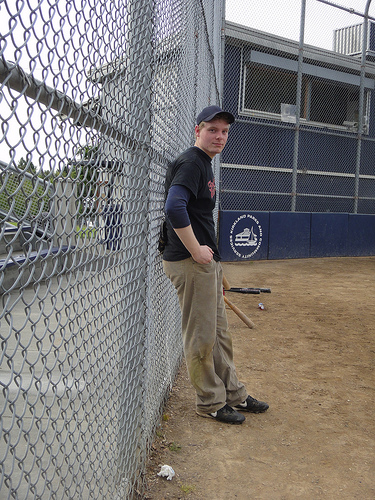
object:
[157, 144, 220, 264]
shirt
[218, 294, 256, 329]
baseball bat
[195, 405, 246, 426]
shoe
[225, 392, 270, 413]
shoe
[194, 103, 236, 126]
cap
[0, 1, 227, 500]
chain-link fence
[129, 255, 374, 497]
field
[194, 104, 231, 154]
head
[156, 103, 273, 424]
man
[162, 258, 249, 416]
pants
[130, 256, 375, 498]
ground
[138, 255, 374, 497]
dirt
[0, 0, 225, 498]
gate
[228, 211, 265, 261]
logo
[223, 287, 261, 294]
bats